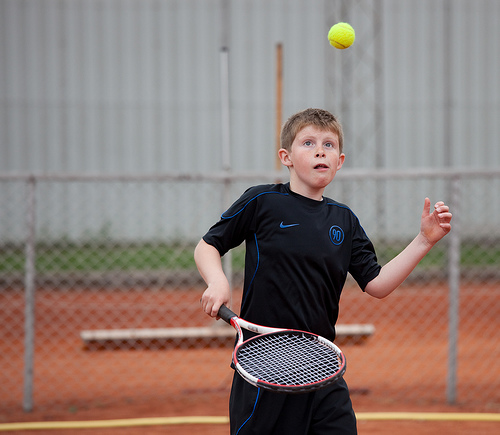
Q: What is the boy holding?
A: A tennis racket.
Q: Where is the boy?
A: On a tennis court.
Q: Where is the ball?
A: In the air.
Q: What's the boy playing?
A: Tennis.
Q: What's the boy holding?
A: Racket.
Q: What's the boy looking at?
A: Tennis ball.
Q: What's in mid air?
A: Tennis ball.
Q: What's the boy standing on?
A: Tennis court.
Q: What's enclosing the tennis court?
A: Chain link fence.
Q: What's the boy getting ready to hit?
A: Tennis ball.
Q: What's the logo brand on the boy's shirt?
A: Nike.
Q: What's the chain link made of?
A: Metal.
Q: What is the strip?
A: Grass.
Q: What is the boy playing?
A: Tennis.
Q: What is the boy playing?
A: Tennis.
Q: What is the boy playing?
A: Tennis.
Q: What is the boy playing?
A: Tennis.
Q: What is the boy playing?
A: Tennis.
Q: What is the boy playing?
A: Tennis.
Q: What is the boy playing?
A: Tennis.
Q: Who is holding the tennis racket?
A: A boy.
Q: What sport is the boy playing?
A: Tennis.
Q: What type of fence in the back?
A: Metal.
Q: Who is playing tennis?
A: The boy.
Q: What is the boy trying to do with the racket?
A: Hit the ball.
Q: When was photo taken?
A: Daytime.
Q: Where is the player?
A: On the court.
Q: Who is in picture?
A: A boy.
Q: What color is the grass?
A: Green.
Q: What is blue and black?
A: Outfit.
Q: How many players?
A: One.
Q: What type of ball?
A: Tennis ball.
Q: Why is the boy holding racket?
A: Hit ball.